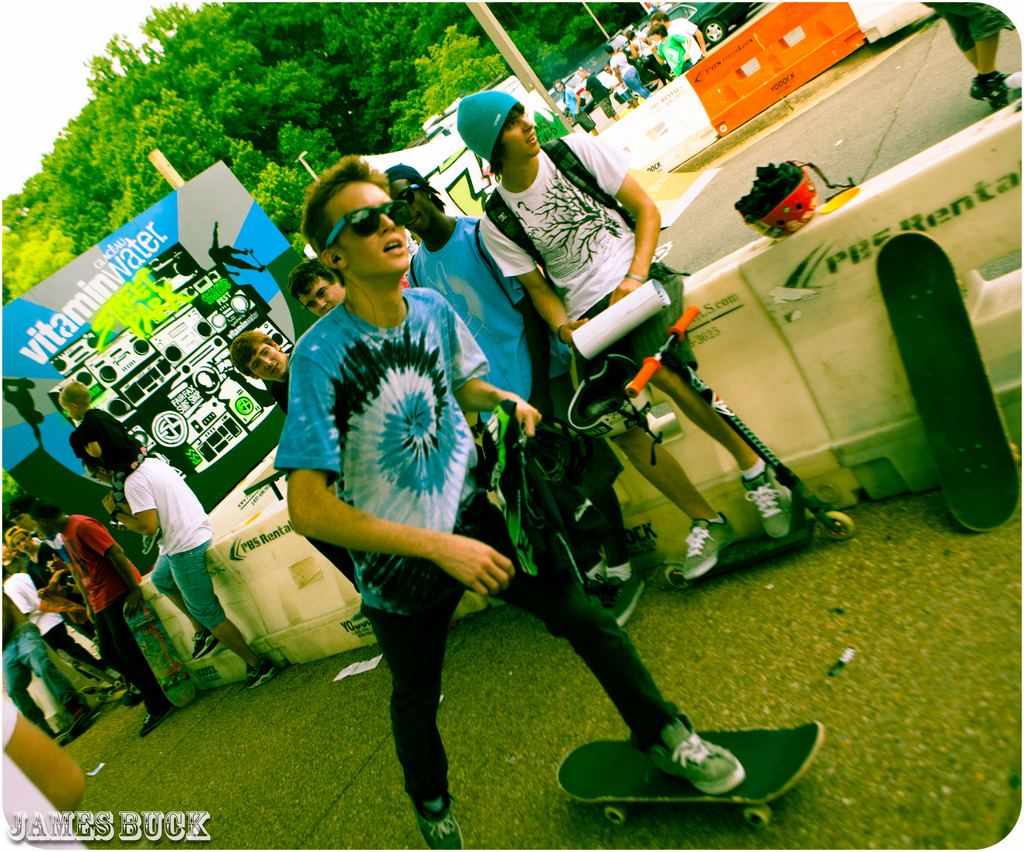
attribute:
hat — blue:
[445, 79, 526, 164]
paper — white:
[318, 641, 388, 689]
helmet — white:
[564, 350, 655, 454]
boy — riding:
[226, 139, 738, 852]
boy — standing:
[449, 102, 826, 638]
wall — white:
[536, 286, 1012, 580]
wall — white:
[192, 521, 361, 666]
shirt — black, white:
[400, 274, 461, 579]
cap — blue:
[410, 93, 540, 189]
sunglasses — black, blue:
[343, 190, 398, 249]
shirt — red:
[15, 505, 160, 652]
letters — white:
[74, 246, 144, 348]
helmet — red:
[720, 168, 839, 249]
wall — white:
[204, 148, 972, 673]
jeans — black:
[380, 529, 677, 808]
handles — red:
[626, 298, 696, 398]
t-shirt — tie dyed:
[268, 287, 502, 607]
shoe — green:
[674, 507, 733, 577]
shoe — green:
[749, 458, 801, 539]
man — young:
[272, 153, 741, 838]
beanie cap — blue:
[454, 90, 521, 171]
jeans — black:
[380, 581, 689, 819]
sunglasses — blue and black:
[325, 191, 418, 244]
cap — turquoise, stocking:
[448, 89, 520, 163]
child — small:
[13, 180, 135, 820]